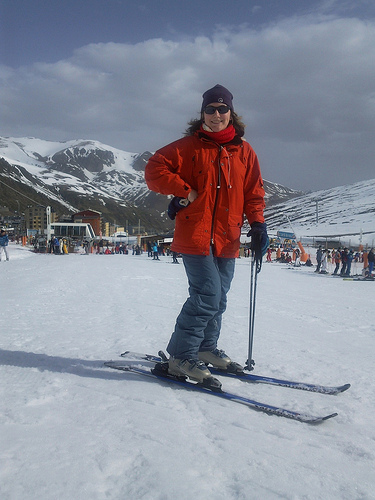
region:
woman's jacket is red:
[141, 106, 281, 273]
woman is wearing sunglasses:
[190, 98, 253, 138]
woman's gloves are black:
[224, 208, 282, 257]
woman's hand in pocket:
[178, 182, 204, 210]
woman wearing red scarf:
[191, 115, 245, 150]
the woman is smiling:
[196, 87, 236, 130]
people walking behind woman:
[10, 205, 371, 308]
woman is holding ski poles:
[233, 210, 266, 369]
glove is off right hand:
[180, 178, 213, 214]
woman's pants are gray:
[158, 234, 241, 352]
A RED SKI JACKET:
[142, 126, 270, 259]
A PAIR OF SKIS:
[102, 347, 354, 427]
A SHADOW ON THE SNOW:
[4, 346, 154, 393]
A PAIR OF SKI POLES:
[240, 231, 264, 377]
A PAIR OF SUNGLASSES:
[197, 100, 237, 120]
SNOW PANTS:
[166, 247, 229, 369]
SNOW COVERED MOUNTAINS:
[8, 134, 156, 205]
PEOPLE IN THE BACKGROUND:
[272, 242, 373, 281]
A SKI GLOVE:
[244, 219, 275, 265]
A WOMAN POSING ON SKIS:
[142, 80, 353, 433]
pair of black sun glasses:
[195, 102, 234, 118]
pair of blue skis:
[100, 326, 372, 452]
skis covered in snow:
[109, 335, 149, 380]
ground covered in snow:
[27, 412, 164, 498]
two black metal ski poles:
[238, 243, 265, 365]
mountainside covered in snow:
[9, 133, 142, 203]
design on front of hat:
[216, 92, 228, 104]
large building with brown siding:
[69, 208, 104, 237]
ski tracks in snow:
[75, 380, 172, 425]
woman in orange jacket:
[138, 76, 269, 384]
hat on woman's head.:
[205, 82, 232, 103]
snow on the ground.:
[42, 446, 76, 472]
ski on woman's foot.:
[230, 408, 328, 420]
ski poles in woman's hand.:
[244, 272, 258, 349]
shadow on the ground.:
[45, 349, 103, 378]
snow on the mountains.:
[41, 140, 67, 170]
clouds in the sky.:
[81, 58, 189, 108]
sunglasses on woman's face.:
[197, 103, 228, 115]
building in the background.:
[28, 207, 44, 228]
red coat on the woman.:
[206, 158, 239, 186]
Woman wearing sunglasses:
[198, 103, 231, 117]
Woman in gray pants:
[177, 236, 224, 349]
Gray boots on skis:
[168, 345, 242, 389]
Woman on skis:
[138, 286, 352, 437]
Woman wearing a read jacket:
[148, 128, 280, 206]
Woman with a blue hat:
[194, 86, 237, 104]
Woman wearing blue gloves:
[244, 218, 278, 251]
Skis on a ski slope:
[111, 312, 336, 434]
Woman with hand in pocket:
[142, 134, 222, 235]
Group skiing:
[310, 239, 370, 286]